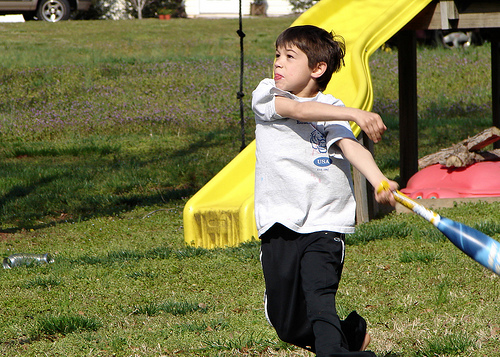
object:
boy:
[253, 24, 399, 357]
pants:
[259, 234, 376, 357]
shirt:
[246, 76, 362, 238]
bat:
[375, 180, 497, 274]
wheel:
[39, 0, 64, 22]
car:
[0, 0, 97, 24]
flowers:
[45, 106, 62, 127]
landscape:
[0, 11, 499, 357]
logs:
[410, 126, 497, 175]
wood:
[414, 125, 499, 173]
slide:
[183, 0, 430, 252]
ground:
[0, 13, 497, 357]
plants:
[161, 9, 168, 18]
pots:
[157, 15, 165, 21]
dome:
[397, 159, 498, 198]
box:
[249, 0, 268, 15]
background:
[0, 0, 499, 357]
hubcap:
[48, 3, 60, 18]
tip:
[375, 178, 389, 194]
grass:
[0, 16, 498, 356]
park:
[0, 12, 498, 357]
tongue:
[273, 71, 282, 82]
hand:
[373, 183, 402, 206]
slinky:
[4, 252, 59, 275]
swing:
[238, 4, 242, 142]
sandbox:
[406, 0, 498, 32]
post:
[394, 42, 421, 189]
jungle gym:
[395, 30, 420, 188]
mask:
[440, 32, 471, 50]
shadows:
[408, 29, 496, 48]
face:
[271, 46, 310, 89]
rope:
[233, 0, 245, 148]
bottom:
[416, 29, 499, 48]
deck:
[414, 0, 499, 32]